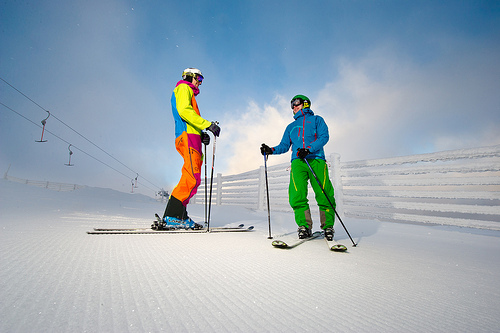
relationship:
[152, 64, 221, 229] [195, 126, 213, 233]
person has ski pole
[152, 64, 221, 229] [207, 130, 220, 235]
person has ski pole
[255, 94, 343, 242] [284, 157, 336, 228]
person wearing pants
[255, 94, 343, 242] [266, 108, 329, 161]
person wearing jacket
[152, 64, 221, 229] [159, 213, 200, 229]
person has ski boot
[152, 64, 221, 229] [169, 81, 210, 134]
person wearing jacket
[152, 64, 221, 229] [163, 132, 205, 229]
person wearing pants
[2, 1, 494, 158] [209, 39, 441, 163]
sky has cloud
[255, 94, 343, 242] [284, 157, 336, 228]
person in pants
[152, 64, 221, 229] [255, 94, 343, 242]
person talking to person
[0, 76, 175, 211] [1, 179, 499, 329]
ski lift above hill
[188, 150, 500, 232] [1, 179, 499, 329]
fence beside hill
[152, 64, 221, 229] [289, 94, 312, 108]
person wearing helmet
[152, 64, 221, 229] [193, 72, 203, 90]
person has face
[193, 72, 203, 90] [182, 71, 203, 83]
face has goggles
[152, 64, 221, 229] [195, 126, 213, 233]
person holding ski pole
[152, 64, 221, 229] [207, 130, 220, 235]
person holding ski pole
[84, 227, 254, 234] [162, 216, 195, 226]
ski on foot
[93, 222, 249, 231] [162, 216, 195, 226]
ski on foot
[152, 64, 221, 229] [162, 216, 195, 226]
person has foot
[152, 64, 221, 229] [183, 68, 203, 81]
person wearing helmet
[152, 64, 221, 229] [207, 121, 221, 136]
person wearing glove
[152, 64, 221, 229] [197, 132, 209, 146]
person wearing glove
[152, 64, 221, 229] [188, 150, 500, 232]
person standing near fence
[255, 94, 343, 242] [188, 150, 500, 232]
person standing near fence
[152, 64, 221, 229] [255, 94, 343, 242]
person skiing with person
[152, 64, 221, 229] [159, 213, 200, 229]
person wearing ski boot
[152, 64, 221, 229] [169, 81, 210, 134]
person in jacket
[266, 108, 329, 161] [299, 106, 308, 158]
jacket has zipper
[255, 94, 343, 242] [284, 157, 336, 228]
person has pants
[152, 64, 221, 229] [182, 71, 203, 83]
person has goggles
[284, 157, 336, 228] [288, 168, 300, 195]
pants have zipper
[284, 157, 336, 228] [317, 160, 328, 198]
pants have zipper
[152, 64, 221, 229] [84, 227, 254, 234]
person standing on ski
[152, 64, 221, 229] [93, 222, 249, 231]
person standing on ski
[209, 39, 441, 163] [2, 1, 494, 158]
cloud in sky